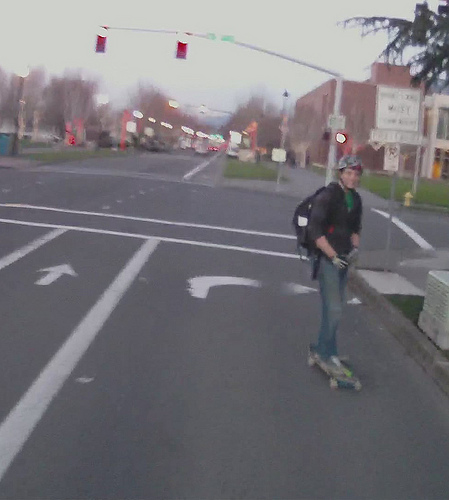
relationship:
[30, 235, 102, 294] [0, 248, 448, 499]
srrow on road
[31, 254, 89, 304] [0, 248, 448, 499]
arrow on road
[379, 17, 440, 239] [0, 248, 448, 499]
tree by road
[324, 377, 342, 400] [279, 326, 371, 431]
wheel of skateboard